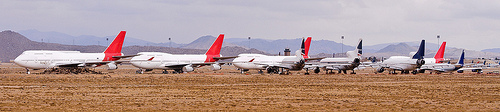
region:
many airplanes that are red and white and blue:
[17, 25, 473, 87]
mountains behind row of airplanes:
[12, 17, 496, 77]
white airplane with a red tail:
[15, 32, 126, 82]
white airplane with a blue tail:
[384, 38, 426, 73]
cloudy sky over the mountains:
[40, 8, 484, 58]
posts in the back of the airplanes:
[71, 31, 470, 51]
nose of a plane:
[15, 40, 42, 68]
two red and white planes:
[26, 23, 230, 80]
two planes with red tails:
[19, 27, 229, 78]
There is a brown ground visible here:
[413, 84, 418, 104]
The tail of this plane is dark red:
[211, 33, 228, 71]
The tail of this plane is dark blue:
[416, 41, 432, 71]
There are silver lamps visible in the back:
[244, 28, 255, 43]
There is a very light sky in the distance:
[331, 12, 353, 54]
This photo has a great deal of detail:
[250, 24, 280, 104]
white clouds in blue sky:
[137, 7, 196, 28]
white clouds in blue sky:
[335, 8, 372, 23]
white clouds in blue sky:
[380, 10, 426, 25]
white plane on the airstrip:
[10, 28, 135, 70]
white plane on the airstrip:
[125, 32, 225, 72]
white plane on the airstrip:
[225, 40, 315, 71]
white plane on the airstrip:
[310, 33, 367, 74]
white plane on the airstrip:
[377, 36, 427, 72]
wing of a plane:
[100, 27, 135, 82]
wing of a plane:
[338, 30, 374, 88]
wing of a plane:
[418, 31, 453, 81]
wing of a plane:
[450, 45, 470, 75]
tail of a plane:
[83, 30, 150, 76]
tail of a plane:
[183, 35, 241, 82]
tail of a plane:
[275, 36, 317, 81]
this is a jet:
[246, 52, 302, 76]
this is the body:
[245, 52, 288, 61]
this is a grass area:
[246, 77, 307, 97]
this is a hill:
[8, 24, 29, 55]